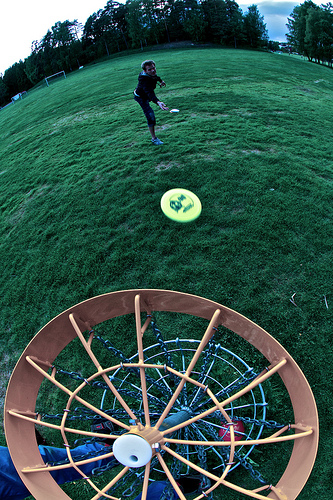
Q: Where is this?
A: This is at the field.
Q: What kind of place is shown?
A: It is a field.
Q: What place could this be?
A: It is a field.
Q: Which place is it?
A: It is a field.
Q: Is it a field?
A: Yes, it is a field.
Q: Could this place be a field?
A: Yes, it is a field.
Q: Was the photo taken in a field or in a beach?
A: It was taken at a field.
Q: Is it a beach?
A: No, it is a field.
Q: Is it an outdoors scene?
A: Yes, it is outdoors.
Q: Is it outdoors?
A: Yes, it is outdoors.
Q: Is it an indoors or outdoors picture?
A: It is outdoors.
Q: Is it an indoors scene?
A: No, it is outdoors.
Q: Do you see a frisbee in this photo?
A: Yes, there is a frisbee.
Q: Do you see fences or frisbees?
A: Yes, there is a frisbee.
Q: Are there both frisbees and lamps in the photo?
A: No, there is a frisbee but no lamps.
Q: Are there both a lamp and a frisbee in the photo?
A: No, there is a frisbee but no lamps.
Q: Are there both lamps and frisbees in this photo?
A: No, there is a frisbee but no lamps.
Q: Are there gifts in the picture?
A: No, there are no gifts.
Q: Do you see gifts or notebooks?
A: No, there are no gifts or notebooks.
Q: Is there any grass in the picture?
A: Yes, there is grass.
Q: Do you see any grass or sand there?
A: Yes, there is grass.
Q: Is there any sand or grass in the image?
A: Yes, there is grass.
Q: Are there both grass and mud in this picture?
A: No, there is grass but no mud.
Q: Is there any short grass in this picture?
A: Yes, there is short grass.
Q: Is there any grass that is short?
A: Yes, there is grass that is short.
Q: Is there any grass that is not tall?
A: Yes, there is short grass.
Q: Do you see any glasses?
A: No, there are no glasses.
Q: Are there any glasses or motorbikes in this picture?
A: No, there are no glasses or motorbikes.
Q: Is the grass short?
A: Yes, the grass is short.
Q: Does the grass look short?
A: Yes, the grass is short.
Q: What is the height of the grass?
A: The grass is short.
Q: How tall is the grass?
A: The grass is short.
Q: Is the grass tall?
A: No, the grass is short.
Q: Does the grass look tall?
A: No, the grass is short.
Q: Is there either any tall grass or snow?
A: No, there is grass but it is short.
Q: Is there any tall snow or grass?
A: No, there is grass but it is short.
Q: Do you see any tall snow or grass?
A: No, there is grass but it is short.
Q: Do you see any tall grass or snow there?
A: No, there is grass but it is short.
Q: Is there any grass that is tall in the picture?
A: No, there is grass but it is short.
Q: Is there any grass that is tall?
A: No, there is grass but it is short.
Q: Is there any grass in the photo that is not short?
A: No, there is grass but it is short.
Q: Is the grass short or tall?
A: The grass is short.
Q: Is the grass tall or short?
A: The grass is short.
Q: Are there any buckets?
A: No, there are no buckets.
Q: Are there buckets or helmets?
A: No, there are no buckets or helmets.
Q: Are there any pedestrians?
A: No, there are no pedestrians.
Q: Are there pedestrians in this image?
A: No, there are no pedestrians.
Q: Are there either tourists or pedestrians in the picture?
A: No, there are no pedestrians or tourists.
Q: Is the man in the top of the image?
A: Yes, the man is in the top of the image.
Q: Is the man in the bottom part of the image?
A: No, the man is in the top of the image.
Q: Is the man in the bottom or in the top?
A: The man is in the top of the image.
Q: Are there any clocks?
A: No, there are no clocks.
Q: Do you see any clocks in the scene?
A: No, there are no clocks.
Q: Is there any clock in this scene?
A: No, there are no clocks.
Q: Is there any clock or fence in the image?
A: No, there are no clocks or fences.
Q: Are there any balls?
A: Yes, there is a ball.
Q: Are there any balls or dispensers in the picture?
A: Yes, there is a ball.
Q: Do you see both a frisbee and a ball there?
A: Yes, there are both a ball and a frisbee.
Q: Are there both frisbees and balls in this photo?
A: Yes, there are both a ball and a frisbee.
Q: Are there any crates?
A: No, there are no crates.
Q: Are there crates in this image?
A: No, there are no crates.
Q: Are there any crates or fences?
A: No, there are no crates or fences.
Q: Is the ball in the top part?
A: No, the ball is in the bottom of the image.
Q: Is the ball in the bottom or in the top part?
A: The ball is in the bottom of the image.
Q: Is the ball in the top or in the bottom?
A: The ball is in the bottom of the image.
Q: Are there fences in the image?
A: No, there are no fences.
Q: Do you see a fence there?
A: No, there are no fences.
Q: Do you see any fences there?
A: No, there are no fences.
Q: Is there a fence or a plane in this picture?
A: No, there are no fences or airplanes.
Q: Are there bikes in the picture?
A: No, there are no bikes.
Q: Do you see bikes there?
A: No, there are no bikes.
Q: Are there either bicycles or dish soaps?
A: No, there are no bicycles or dish soaps.